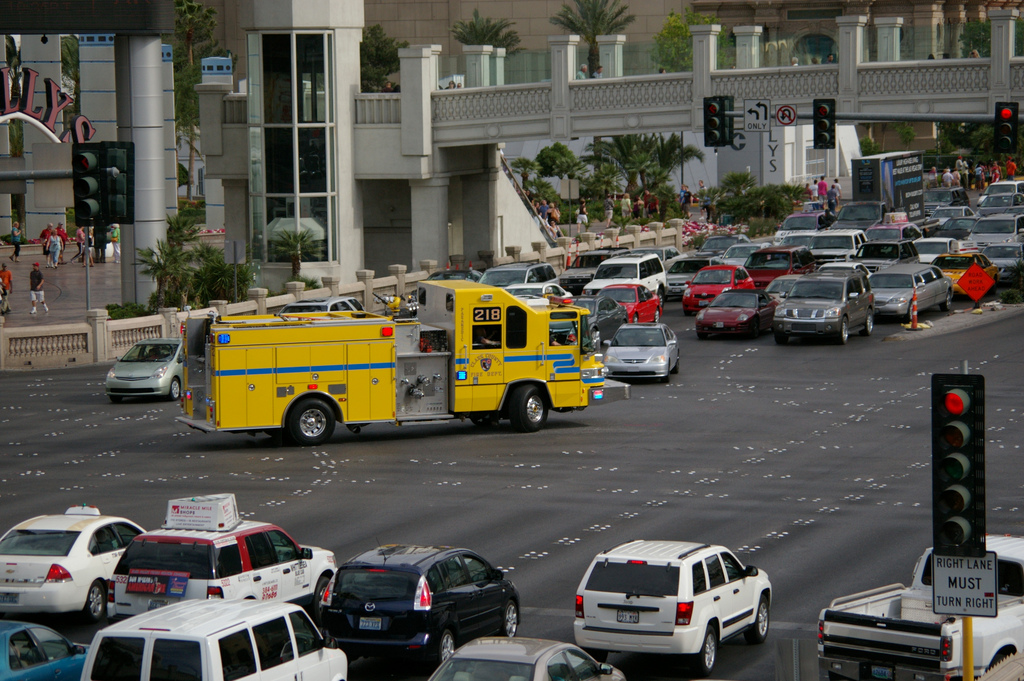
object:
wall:
[362, 179, 490, 277]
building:
[192, 0, 1022, 292]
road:
[0, 205, 1024, 681]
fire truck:
[176, 280, 609, 443]